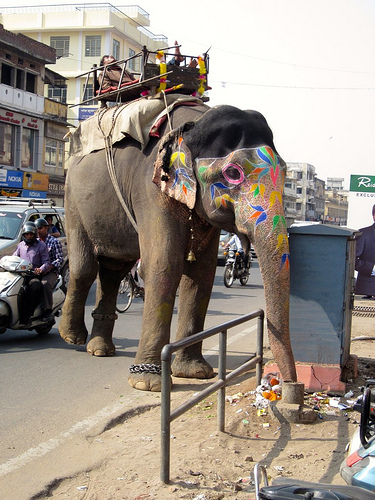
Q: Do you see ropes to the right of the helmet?
A: Yes, there is a rope to the right of the helmet.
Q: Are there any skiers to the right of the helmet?
A: No, there is a rope to the right of the helmet.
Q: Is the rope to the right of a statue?
A: No, the rope is to the right of the helmet.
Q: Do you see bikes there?
A: Yes, there is a bike.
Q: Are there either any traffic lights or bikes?
A: Yes, there is a bike.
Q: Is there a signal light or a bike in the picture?
A: Yes, there is a bike.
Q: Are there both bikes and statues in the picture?
A: No, there is a bike but no statues.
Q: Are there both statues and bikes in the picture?
A: No, there is a bike but no statues.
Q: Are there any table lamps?
A: No, there are no table lamps.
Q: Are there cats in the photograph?
A: No, there are no cats.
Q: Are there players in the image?
A: No, there are no players.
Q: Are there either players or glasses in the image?
A: No, there are no players or glasses.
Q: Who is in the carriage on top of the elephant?
A: The man is in the carriage.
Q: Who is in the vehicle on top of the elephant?
A: The man is in the carriage.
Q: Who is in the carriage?
A: The man is in the carriage.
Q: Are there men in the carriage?
A: Yes, there is a man in the carriage.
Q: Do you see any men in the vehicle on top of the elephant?
A: Yes, there is a man in the carriage.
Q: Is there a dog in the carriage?
A: No, there is a man in the carriage.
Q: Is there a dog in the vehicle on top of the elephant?
A: No, there is a man in the carriage.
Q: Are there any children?
A: No, there are no children.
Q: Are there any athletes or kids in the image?
A: No, there are no kids or athletes.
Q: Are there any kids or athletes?
A: No, there are no kids or athletes.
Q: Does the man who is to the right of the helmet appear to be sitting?
A: Yes, the man is sitting.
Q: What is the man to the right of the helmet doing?
A: The man is sitting.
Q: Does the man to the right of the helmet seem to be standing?
A: No, the man is sitting.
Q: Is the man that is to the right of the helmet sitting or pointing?
A: The man is sitting.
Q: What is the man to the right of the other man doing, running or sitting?
A: The man is sitting.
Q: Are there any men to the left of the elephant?
A: Yes, there is a man to the left of the elephant.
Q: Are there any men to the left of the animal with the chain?
A: Yes, there is a man to the left of the elephant.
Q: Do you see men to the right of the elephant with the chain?
A: No, the man is to the left of the elephant.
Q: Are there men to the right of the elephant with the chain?
A: No, the man is to the left of the elephant.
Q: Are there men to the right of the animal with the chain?
A: No, the man is to the left of the elephant.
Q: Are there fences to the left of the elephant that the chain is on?
A: No, there is a man to the left of the elephant.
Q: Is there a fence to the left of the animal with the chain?
A: No, there is a man to the left of the elephant.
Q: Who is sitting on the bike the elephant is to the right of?
A: The man is sitting on the bike.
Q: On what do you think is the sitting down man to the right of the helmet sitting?
A: The man is sitting on the bike.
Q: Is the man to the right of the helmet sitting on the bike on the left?
A: Yes, the man is sitting on the bike.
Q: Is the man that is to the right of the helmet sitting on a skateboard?
A: No, the man is sitting on the bike.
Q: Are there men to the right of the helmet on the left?
A: Yes, there is a man to the right of the helmet.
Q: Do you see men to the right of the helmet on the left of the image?
A: Yes, there is a man to the right of the helmet.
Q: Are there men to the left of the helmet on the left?
A: No, the man is to the right of the helmet.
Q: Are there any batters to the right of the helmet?
A: No, there is a man to the right of the helmet.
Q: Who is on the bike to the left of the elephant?
A: The man is on the bike.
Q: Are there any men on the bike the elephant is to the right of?
A: Yes, there is a man on the bike.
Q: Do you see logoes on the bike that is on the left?
A: No, there is a man on the bike.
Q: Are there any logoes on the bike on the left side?
A: No, there is a man on the bike.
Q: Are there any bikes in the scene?
A: Yes, there is a bike.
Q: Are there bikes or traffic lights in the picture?
A: Yes, there is a bike.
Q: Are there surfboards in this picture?
A: No, there are no surfboards.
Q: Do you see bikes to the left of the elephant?
A: Yes, there is a bike to the left of the elephant.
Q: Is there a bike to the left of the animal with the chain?
A: Yes, there is a bike to the left of the elephant.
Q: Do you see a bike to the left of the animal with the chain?
A: Yes, there is a bike to the left of the elephant.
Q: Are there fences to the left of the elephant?
A: No, there is a bike to the left of the elephant.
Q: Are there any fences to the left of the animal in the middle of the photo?
A: No, there is a bike to the left of the elephant.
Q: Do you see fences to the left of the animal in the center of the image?
A: No, there is a bike to the left of the elephant.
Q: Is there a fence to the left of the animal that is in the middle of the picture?
A: No, there is a bike to the left of the elephant.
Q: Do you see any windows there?
A: Yes, there is a window.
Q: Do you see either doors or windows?
A: Yes, there is a window.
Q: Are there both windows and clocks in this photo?
A: No, there is a window but no clocks.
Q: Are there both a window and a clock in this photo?
A: No, there is a window but no clocks.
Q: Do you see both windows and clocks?
A: No, there is a window but no clocks.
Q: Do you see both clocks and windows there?
A: No, there is a window but no clocks.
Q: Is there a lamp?
A: No, there are no lamps.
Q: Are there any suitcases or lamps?
A: No, there are no lamps or suitcases.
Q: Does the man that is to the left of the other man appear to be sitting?
A: Yes, the man is sitting.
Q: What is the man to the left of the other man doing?
A: The man is sitting.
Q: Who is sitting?
A: The man is sitting.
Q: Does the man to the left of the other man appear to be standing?
A: No, the man is sitting.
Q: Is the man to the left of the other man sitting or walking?
A: The man is sitting.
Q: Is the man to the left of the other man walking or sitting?
A: The man is sitting.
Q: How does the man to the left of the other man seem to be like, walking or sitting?
A: The man is sitting.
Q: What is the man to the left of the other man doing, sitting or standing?
A: The man is sitting.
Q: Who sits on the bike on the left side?
A: The man sits on the bike.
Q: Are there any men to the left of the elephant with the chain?
A: Yes, there is a man to the left of the elephant.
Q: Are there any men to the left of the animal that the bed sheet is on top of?
A: Yes, there is a man to the left of the elephant.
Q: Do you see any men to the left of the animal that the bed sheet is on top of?
A: Yes, there is a man to the left of the elephant.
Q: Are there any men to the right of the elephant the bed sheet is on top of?
A: No, the man is to the left of the elephant.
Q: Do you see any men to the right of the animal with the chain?
A: No, the man is to the left of the elephant.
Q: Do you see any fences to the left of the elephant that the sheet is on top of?
A: No, there is a man to the left of the elephant.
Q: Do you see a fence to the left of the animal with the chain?
A: No, there is a man to the left of the elephant.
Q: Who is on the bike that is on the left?
A: The man is on the bike.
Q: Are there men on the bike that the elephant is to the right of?
A: Yes, there is a man on the bike.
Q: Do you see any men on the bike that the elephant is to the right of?
A: Yes, there is a man on the bike.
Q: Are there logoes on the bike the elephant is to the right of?
A: No, there is a man on the bike.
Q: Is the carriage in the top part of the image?
A: Yes, the carriage is in the top of the image.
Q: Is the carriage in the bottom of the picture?
A: No, the carriage is in the top of the image.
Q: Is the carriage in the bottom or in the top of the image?
A: The carriage is in the top of the image.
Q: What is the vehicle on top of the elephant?
A: The vehicle is a carriage.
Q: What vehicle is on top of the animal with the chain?
A: The vehicle is a carriage.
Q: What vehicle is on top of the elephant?
A: The vehicle is a carriage.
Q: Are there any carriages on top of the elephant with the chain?
A: Yes, there is a carriage on top of the elephant.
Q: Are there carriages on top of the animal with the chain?
A: Yes, there is a carriage on top of the elephant.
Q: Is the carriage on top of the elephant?
A: Yes, the carriage is on top of the elephant.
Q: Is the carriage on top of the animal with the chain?
A: Yes, the carriage is on top of the elephant.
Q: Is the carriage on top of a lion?
A: No, the carriage is on top of the elephant.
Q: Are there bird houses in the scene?
A: No, there are no bird houses.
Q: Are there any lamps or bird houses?
A: No, there are no bird houses or lamps.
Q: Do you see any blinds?
A: No, there are no blinds.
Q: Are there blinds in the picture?
A: No, there are no blinds.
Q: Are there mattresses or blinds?
A: No, there are no blinds or mattresses.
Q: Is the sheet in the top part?
A: Yes, the sheet is in the top of the image.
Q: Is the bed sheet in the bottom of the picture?
A: No, the bed sheet is in the top of the image.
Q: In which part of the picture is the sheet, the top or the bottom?
A: The sheet is in the top of the image.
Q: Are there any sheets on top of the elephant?
A: Yes, there is a sheet on top of the elephant.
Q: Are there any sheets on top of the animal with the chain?
A: Yes, there is a sheet on top of the elephant.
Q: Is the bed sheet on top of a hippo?
A: No, the bed sheet is on top of the elephant.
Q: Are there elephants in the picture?
A: Yes, there is an elephant.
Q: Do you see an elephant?
A: Yes, there is an elephant.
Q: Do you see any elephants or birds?
A: Yes, there is an elephant.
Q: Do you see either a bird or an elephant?
A: Yes, there is an elephant.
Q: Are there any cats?
A: No, there are no cats.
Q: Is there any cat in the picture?
A: No, there are no cats.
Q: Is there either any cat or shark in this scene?
A: No, there are no cats or sharks.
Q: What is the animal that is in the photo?
A: The animal is an elephant.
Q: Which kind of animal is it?
A: The animal is an elephant.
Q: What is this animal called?
A: This is an elephant.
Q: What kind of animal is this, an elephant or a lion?
A: This is an elephant.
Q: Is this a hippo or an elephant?
A: This is an elephant.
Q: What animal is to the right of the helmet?
A: The animal is an elephant.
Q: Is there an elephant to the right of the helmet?
A: Yes, there is an elephant to the right of the helmet.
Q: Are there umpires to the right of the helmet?
A: No, there is an elephant to the right of the helmet.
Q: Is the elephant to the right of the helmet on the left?
A: Yes, the elephant is to the right of the helmet.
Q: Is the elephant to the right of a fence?
A: No, the elephant is to the right of the helmet.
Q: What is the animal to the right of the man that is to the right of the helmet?
A: The animal is an elephant.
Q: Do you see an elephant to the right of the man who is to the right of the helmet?
A: Yes, there is an elephant to the right of the man.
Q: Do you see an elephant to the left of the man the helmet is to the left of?
A: No, the elephant is to the right of the man.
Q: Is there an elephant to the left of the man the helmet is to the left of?
A: No, the elephant is to the right of the man.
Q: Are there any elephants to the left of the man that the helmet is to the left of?
A: No, the elephant is to the right of the man.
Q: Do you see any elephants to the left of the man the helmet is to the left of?
A: No, the elephant is to the right of the man.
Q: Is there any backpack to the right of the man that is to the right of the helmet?
A: No, there is an elephant to the right of the man.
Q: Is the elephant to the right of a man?
A: Yes, the elephant is to the right of a man.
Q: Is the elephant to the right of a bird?
A: No, the elephant is to the right of a man.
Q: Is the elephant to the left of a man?
A: No, the elephant is to the right of a man.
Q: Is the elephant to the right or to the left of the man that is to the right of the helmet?
A: The elephant is to the right of the man.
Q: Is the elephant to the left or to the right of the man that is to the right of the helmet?
A: The elephant is to the right of the man.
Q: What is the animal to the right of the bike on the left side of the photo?
A: The animal is an elephant.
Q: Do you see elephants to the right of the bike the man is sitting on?
A: Yes, there is an elephant to the right of the bike.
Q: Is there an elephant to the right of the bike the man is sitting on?
A: Yes, there is an elephant to the right of the bike.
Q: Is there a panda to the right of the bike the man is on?
A: No, there is an elephant to the right of the bike.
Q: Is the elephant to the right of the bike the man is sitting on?
A: Yes, the elephant is to the right of the bike.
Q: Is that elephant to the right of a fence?
A: No, the elephant is to the right of the bike.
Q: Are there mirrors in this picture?
A: No, there are no mirrors.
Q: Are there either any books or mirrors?
A: No, there are no mirrors or books.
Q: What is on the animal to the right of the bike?
A: The chain is on the elephant.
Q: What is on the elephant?
A: The chain is on the elephant.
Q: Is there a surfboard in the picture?
A: No, there are no surfboards.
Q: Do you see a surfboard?
A: No, there are no surfboards.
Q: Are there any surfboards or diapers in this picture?
A: No, there are no surfboards or diapers.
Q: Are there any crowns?
A: No, there are no crowns.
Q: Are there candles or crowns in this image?
A: No, there are no crowns or candles.